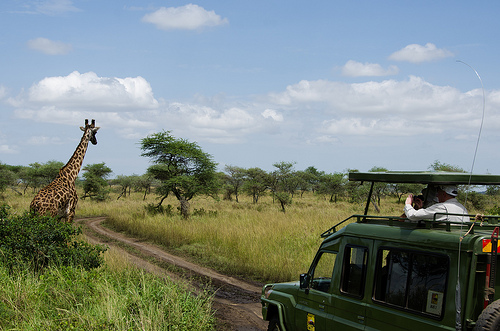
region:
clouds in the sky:
[38, 63, 446, 134]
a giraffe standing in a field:
[35, 123, 112, 213]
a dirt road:
[84, 200, 246, 326]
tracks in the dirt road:
[116, 226, 163, 286]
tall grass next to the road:
[24, 261, 174, 325]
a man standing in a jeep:
[401, 174, 483, 256]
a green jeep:
[217, 213, 493, 308]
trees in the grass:
[149, 133, 331, 194]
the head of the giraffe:
[84, 118, 104, 147]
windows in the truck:
[346, 239, 456, 314]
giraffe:
[15, 98, 132, 242]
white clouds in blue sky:
[38, 25, 120, 73]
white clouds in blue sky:
[261, 73, 299, 97]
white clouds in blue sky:
[367, 15, 465, 86]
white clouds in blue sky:
[270, 12, 317, 52]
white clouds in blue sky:
[381, 35, 441, 107]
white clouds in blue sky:
[182, 21, 264, 93]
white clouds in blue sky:
[80, 42, 145, 84]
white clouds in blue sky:
[221, 52, 333, 154]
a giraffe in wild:
[26, 109, 100, 224]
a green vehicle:
[259, 170, 499, 329]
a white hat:
[431, 179, 460, 194]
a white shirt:
[403, 200, 471, 220]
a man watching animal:
[404, 183, 467, 224]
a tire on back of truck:
[474, 298, 498, 328]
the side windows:
[304, 234, 452, 319]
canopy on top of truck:
[348, 168, 498, 215]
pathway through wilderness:
[85, 213, 271, 329]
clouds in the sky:
[2, 13, 496, 171]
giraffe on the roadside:
[25, 98, 101, 229]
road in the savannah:
[77, 215, 256, 302]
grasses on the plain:
[132, 187, 321, 256]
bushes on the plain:
[4, 208, 97, 271]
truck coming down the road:
[251, 153, 498, 326]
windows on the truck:
[379, 253, 444, 303]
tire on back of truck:
[464, 285, 499, 328]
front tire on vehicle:
[258, 309, 278, 329]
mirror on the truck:
[301, 271, 315, 291]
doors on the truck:
[301, 291, 362, 328]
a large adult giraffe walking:
[11, 105, 93, 245]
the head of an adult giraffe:
[71, 115, 106, 146]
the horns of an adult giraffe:
[80, 106, 96, 131]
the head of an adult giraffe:
[65, 118, 85, 129]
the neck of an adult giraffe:
[54, 136, 95, 173]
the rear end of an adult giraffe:
[15, 182, 49, 216]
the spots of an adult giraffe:
[55, 195, 72, 210]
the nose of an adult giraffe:
[85, 133, 99, 145]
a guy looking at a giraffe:
[282, 138, 497, 323]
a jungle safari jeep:
[260, 215, 425, 329]